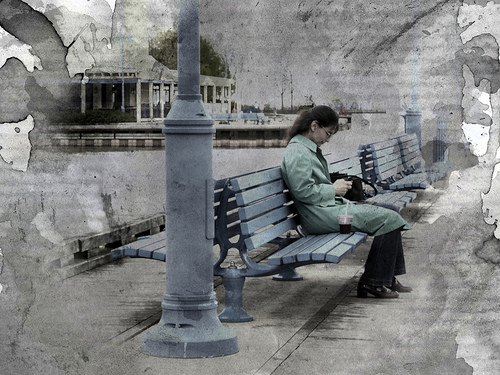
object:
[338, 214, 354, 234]
cup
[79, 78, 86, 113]
pillars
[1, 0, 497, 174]
wall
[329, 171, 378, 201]
bag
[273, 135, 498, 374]
street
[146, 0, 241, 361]
pole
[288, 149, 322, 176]
jacket part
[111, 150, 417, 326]
bench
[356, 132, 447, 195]
bench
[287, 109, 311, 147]
pony tail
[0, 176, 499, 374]
ground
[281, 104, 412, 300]
person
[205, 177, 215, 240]
panel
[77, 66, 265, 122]
building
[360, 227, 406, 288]
black pants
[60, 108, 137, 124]
bush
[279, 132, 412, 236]
coat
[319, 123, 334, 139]
eyeglasses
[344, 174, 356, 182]
straw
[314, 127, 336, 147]
face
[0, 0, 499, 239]
background